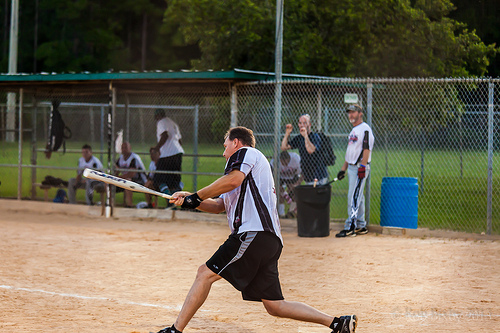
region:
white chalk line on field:
[2, 275, 190, 317]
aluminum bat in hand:
[77, 160, 169, 204]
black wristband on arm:
[182, 192, 203, 210]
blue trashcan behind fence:
[378, 170, 422, 231]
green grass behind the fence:
[438, 176, 487, 229]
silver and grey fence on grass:
[419, 76, 497, 229]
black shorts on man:
[208, 228, 298, 304]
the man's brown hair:
[230, 129, 255, 142]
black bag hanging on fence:
[43, 98, 73, 158]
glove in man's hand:
[148, 137, 162, 162]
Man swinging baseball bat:
[80, 126, 359, 331]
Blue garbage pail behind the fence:
[381, 174, 421, 226]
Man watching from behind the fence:
[283, 106, 336, 241]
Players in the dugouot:
[71, 103, 177, 208]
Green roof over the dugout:
[0, 64, 284, 83]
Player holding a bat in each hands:
[318, 98, 373, 239]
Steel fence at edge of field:
[231, 79, 498, 239]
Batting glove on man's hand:
[358, 162, 365, 184]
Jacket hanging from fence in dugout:
[42, 97, 62, 157]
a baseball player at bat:
[16, 18, 449, 322]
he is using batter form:
[69, 115, 370, 331]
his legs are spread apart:
[156, 251, 369, 331]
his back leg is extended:
[247, 271, 367, 331]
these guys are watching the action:
[278, 92, 403, 254]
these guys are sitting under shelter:
[11, 56, 196, 220]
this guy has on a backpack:
[279, 112, 339, 177]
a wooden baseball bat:
[79, 146, 179, 215]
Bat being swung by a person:
[83, 165, 183, 202]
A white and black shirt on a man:
[222, 143, 284, 246]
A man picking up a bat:
[319, 103, 373, 236]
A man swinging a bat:
[84, 125, 357, 330]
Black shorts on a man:
[206, 230, 284, 307]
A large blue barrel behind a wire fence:
[378, 173, 420, 231]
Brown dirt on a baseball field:
[3, 207, 498, 331]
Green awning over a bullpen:
[0, 65, 383, 92]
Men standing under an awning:
[53, 105, 190, 211]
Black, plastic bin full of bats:
[294, 181, 333, 236]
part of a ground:
[295, 224, 327, 259]